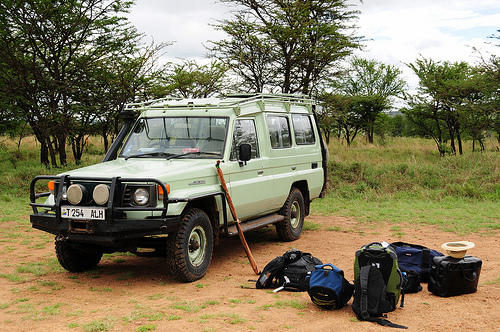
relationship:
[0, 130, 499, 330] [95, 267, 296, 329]
ground with dirt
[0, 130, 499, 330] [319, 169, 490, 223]
ground with grass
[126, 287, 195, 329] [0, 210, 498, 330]
grass in dirt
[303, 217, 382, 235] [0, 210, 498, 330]
grass in dirt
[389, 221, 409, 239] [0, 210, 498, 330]
grass in dirt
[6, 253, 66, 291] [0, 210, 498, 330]
grass in dirt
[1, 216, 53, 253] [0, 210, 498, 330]
grass in dirt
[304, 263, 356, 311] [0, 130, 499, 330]
back pack on ground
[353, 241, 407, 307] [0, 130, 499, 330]
backpack on ground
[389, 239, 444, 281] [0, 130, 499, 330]
bag on ground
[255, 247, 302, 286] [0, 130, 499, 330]
bag on ground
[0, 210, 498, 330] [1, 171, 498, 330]
dirt on ground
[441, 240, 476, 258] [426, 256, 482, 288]
hat on top of bag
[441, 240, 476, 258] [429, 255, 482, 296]
hat on top of bag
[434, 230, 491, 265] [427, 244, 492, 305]
hat on top of bag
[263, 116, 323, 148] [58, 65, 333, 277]
windows on jeep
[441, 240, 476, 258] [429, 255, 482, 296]
hat on bag